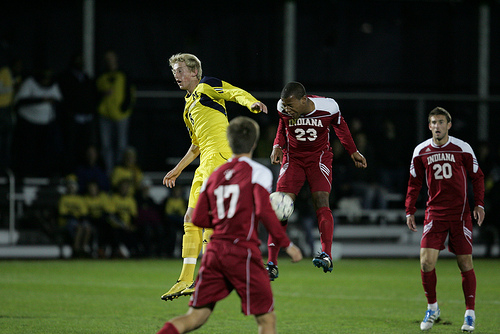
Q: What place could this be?
A: It is a field.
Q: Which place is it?
A: It is a field.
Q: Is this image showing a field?
A: Yes, it is showing a field.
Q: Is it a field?
A: Yes, it is a field.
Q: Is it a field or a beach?
A: It is a field.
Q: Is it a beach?
A: No, it is a field.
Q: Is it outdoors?
A: Yes, it is outdoors.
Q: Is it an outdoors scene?
A: Yes, it is outdoors.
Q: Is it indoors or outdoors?
A: It is outdoors.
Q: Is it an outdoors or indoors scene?
A: It is outdoors.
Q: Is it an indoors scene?
A: No, it is outdoors.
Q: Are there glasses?
A: No, there are no glasses.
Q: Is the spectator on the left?
A: Yes, the spectator is on the left of the image.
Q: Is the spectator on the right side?
A: No, the spectator is on the left of the image.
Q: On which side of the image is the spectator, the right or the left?
A: The spectator is on the left of the image.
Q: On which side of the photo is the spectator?
A: The spectator is on the left of the image.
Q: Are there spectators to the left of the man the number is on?
A: Yes, there is a spectator to the left of the man.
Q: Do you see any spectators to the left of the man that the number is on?
A: Yes, there is a spectator to the left of the man.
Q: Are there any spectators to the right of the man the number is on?
A: No, the spectator is to the left of the man.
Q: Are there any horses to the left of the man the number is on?
A: No, there is a spectator to the left of the man.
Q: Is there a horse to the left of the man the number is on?
A: No, there is a spectator to the left of the man.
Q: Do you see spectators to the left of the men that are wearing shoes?
A: Yes, there is a spectator to the left of the men.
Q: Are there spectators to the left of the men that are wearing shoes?
A: Yes, there is a spectator to the left of the men.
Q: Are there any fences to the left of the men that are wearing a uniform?
A: No, there is a spectator to the left of the men.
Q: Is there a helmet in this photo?
A: No, there are no helmets.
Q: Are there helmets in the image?
A: No, there are no helmets.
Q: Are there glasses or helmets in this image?
A: No, there are no helmets or glasses.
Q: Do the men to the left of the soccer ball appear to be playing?
A: Yes, the men are playing.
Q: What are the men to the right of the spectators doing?
A: The men are playing.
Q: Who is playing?
A: The men are playing.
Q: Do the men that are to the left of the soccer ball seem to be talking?
A: No, the men are playing.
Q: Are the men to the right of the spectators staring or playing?
A: The men are playing.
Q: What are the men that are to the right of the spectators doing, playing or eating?
A: The men are playing.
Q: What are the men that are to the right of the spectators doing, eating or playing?
A: The men are playing.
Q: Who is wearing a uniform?
A: The men are wearing a uniform.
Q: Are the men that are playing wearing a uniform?
A: Yes, the men are wearing a uniform.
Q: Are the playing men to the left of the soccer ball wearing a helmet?
A: No, the men are wearing a uniform.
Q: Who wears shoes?
A: The men wear shoes.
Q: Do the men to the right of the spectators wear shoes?
A: Yes, the men wear shoes.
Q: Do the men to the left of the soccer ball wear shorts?
A: No, the men wear shoes.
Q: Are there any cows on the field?
A: No, there are men on the field.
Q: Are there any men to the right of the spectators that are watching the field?
A: Yes, there are men to the right of the spectators.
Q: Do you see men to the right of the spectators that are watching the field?
A: Yes, there are men to the right of the spectators.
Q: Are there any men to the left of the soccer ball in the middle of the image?
A: Yes, there are men to the left of the soccer ball.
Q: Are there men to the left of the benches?
A: Yes, there are men to the left of the benches.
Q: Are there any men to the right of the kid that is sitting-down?
A: Yes, there are men to the right of the kid.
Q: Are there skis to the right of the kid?
A: No, there are men to the right of the kid.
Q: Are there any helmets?
A: No, there are no helmets.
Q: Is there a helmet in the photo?
A: No, there are no helmets.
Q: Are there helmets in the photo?
A: No, there are no helmets.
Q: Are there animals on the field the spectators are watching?
A: No, there is a man on the field.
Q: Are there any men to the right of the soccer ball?
A: Yes, there is a man to the right of the soccer ball.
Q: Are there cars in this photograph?
A: No, there are no cars.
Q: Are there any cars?
A: No, there are no cars.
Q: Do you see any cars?
A: No, there are no cars.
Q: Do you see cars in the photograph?
A: No, there are no cars.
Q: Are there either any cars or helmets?
A: No, there are no cars or helmets.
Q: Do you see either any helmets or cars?
A: No, there are no cars or helmets.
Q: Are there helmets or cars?
A: No, there are no cars or helmets.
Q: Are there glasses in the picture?
A: No, there are no glasses.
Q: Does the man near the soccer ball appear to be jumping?
A: Yes, the man is jumping.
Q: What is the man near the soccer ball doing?
A: The man is jumping.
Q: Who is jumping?
A: The man is jumping.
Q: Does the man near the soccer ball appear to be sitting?
A: No, the man is jumping.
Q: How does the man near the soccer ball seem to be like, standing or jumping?
A: The man is jumping.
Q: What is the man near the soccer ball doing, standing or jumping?
A: The man is jumping.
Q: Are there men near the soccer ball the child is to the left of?
A: Yes, there is a man near the soccer ball.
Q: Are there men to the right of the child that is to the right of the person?
A: Yes, there is a man to the right of the child.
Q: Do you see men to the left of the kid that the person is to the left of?
A: No, the man is to the right of the kid.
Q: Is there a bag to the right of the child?
A: No, there is a man to the right of the child.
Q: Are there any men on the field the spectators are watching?
A: Yes, there is a man on the field.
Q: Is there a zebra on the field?
A: No, there is a man on the field.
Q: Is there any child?
A: Yes, there is a child.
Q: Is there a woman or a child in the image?
A: Yes, there is a child.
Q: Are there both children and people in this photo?
A: Yes, there are both a child and a person.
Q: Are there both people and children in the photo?
A: Yes, there are both a child and a person.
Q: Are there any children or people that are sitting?
A: Yes, the child is sitting.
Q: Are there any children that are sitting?
A: Yes, there is a child that is sitting.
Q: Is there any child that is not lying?
A: Yes, there is a child that is sitting.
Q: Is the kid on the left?
A: Yes, the kid is on the left of the image.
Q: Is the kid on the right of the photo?
A: No, the kid is on the left of the image.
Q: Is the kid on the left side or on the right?
A: The kid is on the left of the image.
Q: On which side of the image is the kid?
A: The kid is on the left of the image.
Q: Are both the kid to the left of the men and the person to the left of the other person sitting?
A: Yes, both the kid and the person are sitting.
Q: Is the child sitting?
A: Yes, the child is sitting.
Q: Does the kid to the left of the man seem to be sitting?
A: Yes, the kid is sitting.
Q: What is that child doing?
A: The child is sitting.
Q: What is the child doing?
A: The child is sitting.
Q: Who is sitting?
A: The kid is sitting.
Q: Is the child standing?
A: No, the child is sitting.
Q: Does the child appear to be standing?
A: No, the child is sitting.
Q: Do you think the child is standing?
A: No, the child is sitting.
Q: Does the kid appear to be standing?
A: No, the kid is sitting.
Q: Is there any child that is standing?
A: No, there is a child but he is sitting.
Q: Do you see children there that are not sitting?
A: No, there is a child but he is sitting.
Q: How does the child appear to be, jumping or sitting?
A: The child is sitting.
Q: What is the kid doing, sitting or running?
A: The kid is sitting.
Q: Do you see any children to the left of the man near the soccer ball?
A: Yes, there is a child to the left of the man.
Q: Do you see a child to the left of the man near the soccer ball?
A: Yes, there is a child to the left of the man.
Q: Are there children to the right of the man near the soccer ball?
A: No, the child is to the left of the man.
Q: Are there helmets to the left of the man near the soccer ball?
A: No, there is a child to the left of the man.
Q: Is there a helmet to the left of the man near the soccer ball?
A: No, there is a child to the left of the man.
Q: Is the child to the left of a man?
A: Yes, the child is to the left of a man.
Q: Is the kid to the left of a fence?
A: No, the kid is to the left of a man.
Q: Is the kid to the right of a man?
A: No, the kid is to the left of a man.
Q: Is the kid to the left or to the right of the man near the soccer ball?
A: The kid is to the left of the man.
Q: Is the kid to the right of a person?
A: Yes, the kid is to the right of a person.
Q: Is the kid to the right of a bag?
A: No, the kid is to the right of a person.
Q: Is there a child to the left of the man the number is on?
A: Yes, there is a child to the left of the man.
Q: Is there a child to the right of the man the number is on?
A: No, the child is to the left of the man.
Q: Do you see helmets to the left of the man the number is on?
A: No, there is a child to the left of the man.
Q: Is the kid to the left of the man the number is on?
A: Yes, the kid is to the left of the man.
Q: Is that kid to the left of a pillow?
A: No, the kid is to the left of the man.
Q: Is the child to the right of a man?
A: No, the child is to the left of a man.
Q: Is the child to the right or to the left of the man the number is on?
A: The child is to the left of the man.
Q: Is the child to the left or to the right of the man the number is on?
A: The child is to the left of the man.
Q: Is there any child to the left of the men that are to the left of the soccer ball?
A: Yes, there is a child to the left of the men.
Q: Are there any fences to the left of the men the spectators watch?
A: No, there is a child to the left of the men.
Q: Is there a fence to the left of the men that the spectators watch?
A: No, there is a child to the left of the men.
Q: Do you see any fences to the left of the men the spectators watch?
A: No, there is a child to the left of the men.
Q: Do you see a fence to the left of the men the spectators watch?
A: No, there is a child to the left of the men.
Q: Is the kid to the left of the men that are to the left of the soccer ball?
A: Yes, the kid is to the left of the men.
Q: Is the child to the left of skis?
A: No, the child is to the left of the men.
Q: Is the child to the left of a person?
A: No, the child is to the right of a person.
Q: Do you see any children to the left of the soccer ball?
A: Yes, there is a child to the left of the soccer ball.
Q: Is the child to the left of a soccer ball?
A: Yes, the child is to the left of a soccer ball.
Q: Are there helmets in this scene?
A: No, there are no helmets.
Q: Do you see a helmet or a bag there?
A: No, there are no helmets or bags.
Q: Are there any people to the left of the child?
A: Yes, there is a person to the left of the child.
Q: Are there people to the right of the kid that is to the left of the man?
A: No, the person is to the left of the kid.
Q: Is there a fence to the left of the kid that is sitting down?
A: No, there is a person to the left of the kid.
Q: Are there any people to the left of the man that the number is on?
A: Yes, there is a person to the left of the man.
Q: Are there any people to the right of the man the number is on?
A: No, the person is to the left of the man.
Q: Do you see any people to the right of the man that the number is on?
A: No, the person is to the left of the man.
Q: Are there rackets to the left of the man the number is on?
A: No, there is a person to the left of the man.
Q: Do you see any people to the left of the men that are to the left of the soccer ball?
A: Yes, there is a person to the left of the men.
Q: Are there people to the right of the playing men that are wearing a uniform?
A: No, the person is to the left of the men.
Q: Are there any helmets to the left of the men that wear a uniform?
A: No, there is a person to the left of the men.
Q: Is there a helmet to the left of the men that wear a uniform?
A: No, there is a person to the left of the men.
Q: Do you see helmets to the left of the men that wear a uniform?
A: No, there is a person to the left of the men.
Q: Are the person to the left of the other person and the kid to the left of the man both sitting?
A: Yes, both the person and the kid are sitting.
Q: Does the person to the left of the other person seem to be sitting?
A: Yes, the person is sitting.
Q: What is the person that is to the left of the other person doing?
A: The person is sitting.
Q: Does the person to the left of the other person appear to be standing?
A: No, the person is sitting.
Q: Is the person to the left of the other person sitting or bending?
A: The person is sitting.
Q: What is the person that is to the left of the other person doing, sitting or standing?
A: The person is sitting.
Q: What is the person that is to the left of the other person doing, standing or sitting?
A: The person is sitting.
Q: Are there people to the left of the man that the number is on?
A: Yes, there is a person to the left of the man.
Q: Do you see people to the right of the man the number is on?
A: No, the person is to the left of the man.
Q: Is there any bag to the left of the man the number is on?
A: No, there is a person to the left of the man.